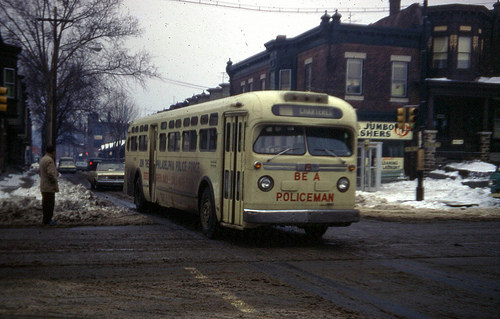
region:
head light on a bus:
[252, 170, 275, 192]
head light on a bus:
[335, 175, 355, 194]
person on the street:
[30, 134, 70, 232]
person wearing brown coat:
[32, 140, 69, 232]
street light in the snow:
[389, 96, 436, 213]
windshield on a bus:
[248, 120, 360, 165]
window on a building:
[381, 53, 420, 103]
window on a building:
[336, 51, 372, 106]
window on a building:
[451, 23, 475, 78]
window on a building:
[293, 55, 320, 99]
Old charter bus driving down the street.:
[122, 87, 363, 245]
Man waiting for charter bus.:
[32, 87, 380, 252]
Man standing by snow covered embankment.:
[2, 138, 147, 228]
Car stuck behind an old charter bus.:
[82, 92, 368, 247]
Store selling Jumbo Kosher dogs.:
[225, 11, 425, 202]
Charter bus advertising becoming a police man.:
[119, 86, 368, 257]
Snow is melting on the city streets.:
[0, 220, 499, 316]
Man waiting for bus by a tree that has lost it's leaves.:
[1, 0, 171, 232]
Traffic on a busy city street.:
[56, 91, 382, 246]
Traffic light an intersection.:
[392, 0, 456, 216]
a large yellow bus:
[122, 88, 364, 229]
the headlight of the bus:
[254, 172, 276, 194]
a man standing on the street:
[36, 143, 61, 230]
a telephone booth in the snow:
[355, 138, 389, 195]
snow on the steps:
[427, 164, 494, 208]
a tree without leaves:
[5, 1, 127, 149]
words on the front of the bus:
[272, 163, 341, 212]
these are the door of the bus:
[217, 109, 248, 225]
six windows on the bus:
[127, 127, 218, 154]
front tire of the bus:
[195, 177, 219, 238]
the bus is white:
[116, 83, 378, 244]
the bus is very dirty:
[116, 86, 363, 246]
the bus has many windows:
[120, 108, 222, 159]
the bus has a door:
[212, 107, 256, 239]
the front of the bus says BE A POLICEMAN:
[268, 163, 343, 212]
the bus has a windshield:
[247, 117, 359, 163]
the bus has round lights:
[253, 170, 351, 195]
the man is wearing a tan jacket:
[33, 151, 58, 197]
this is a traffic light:
[386, 97, 431, 204]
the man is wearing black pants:
[38, 190, 60, 227]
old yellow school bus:
[116, 90, 351, 226]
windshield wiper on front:
[258, 148, 300, 169]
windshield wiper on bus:
[313, 148, 346, 169]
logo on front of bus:
[263, 184, 336, 204]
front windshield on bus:
[251, 129, 347, 154]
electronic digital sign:
[266, 103, 338, 115]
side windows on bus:
[128, 118, 230, 154]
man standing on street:
[31, 146, 60, 224]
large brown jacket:
[31, 156, 61, 191]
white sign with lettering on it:
[361, 120, 422, 140]